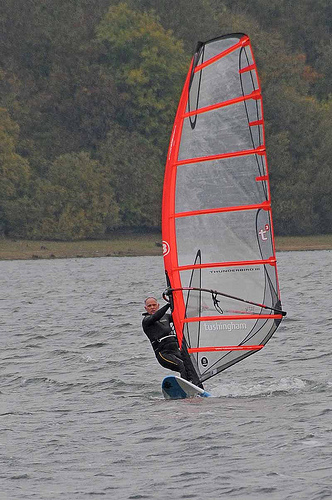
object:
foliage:
[115, 18, 162, 90]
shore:
[2, 237, 331, 258]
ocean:
[0, 247, 331, 498]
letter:
[239, 321, 246, 330]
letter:
[203, 321, 208, 333]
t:
[257, 227, 268, 240]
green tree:
[31, 150, 123, 242]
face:
[145, 297, 157, 315]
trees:
[90, 0, 190, 137]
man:
[140, 294, 203, 389]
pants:
[154, 342, 201, 387]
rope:
[208, 289, 222, 313]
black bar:
[162, 287, 286, 316]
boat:
[160, 31, 287, 397]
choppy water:
[0, 246, 331, 498]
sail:
[161, 31, 287, 384]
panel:
[161, 373, 210, 398]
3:
[264, 223, 270, 229]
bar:
[180, 312, 281, 322]